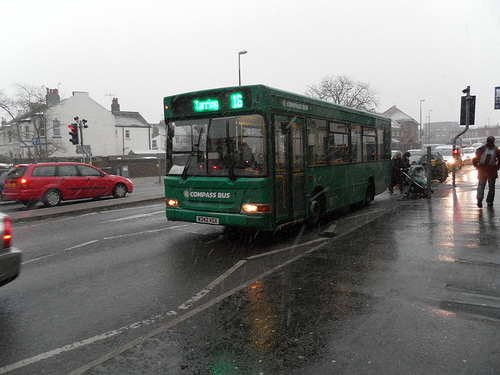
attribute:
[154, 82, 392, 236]
bus — green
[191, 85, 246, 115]
sign — Bright green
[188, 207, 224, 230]
license plate — white , Black 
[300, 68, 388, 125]
tree — bare , leafless 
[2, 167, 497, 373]
road — wet , slick 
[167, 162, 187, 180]
sign — white 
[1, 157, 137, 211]
station wagon — red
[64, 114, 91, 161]
stoplight — red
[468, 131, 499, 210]
man — walking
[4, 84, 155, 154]
townhouses — white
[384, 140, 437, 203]
bus — green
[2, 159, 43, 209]
car — Bright red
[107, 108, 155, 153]
building — Two story, white 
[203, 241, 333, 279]
line — triangular 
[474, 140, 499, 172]
backpack — black, white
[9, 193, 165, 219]
barrier — in the street